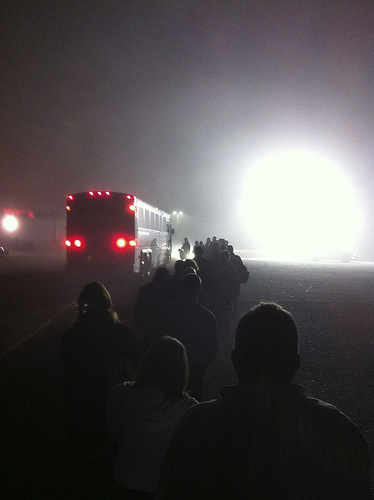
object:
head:
[233, 301, 300, 388]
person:
[166, 301, 368, 499]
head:
[141, 336, 189, 387]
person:
[104, 336, 198, 497]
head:
[77, 283, 119, 327]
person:
[62, 282, 126, 414]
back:
[153, 265, 169, 285]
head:
[152, 267, 173, 289]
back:
[229, 302, 301, 386]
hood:
[121, 384, 192, 416]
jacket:
[113, 382, 199, 498]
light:
[226, 137, 373, 267]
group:
[50, 237, 370, 499]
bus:
[65, 191, 172, 275]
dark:
[0, 3, 373, 500]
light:
[0, 208, 20, 234]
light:
[116, 238, 126, 250]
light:
[73, 238, 82, 248]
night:
[2, 2, 372, 275]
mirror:
[169, 228, 178, 236]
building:
[212, 138, 374, 267]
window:
[139, 208, 144, 228]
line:
[133, 234, 247, 375]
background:
[0, 0, 372, 305]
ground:
[3, 260, 372, 500]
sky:
[0, 0, 373, 198]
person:
[179, 236, 193, 261]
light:
[125, 193, 134, 202]